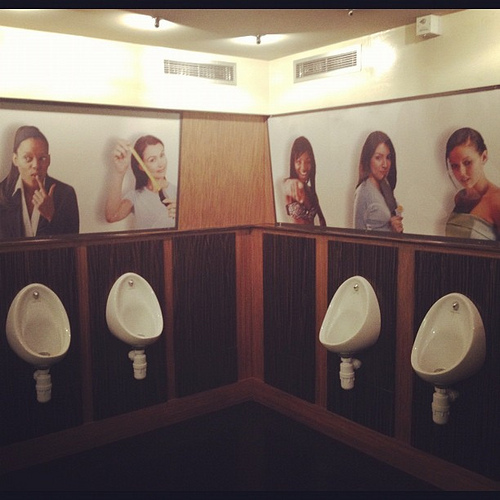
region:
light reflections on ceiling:
[113, 9, 305, 65]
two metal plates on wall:
[159, 45, 365, 109]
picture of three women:
[271, 95, 498, 230]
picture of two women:
[2, 104, 183, 244]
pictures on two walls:
[2, 86, 498, 465]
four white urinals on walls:
[5, 268, 483, 381]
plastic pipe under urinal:
[412, 346, 478, 425]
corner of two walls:
[203, 55, 312, 417]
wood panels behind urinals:
[4, 228, 498, 470]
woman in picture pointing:
[268, 129, 335, 229]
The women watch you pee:
[22, 103, 483, 273]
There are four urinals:
[7, 252, 487, 425]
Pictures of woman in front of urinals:
[26, 109, 494, 413]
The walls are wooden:
[75, 225, 390, 460]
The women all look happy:
[10, 109, 488, 286]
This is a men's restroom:
[14, 80, 494, 448]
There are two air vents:
[100, 33, 377, 125]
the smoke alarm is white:
[412, 10, 443, 50]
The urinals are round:
[417, 287, 477, 433]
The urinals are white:
[294, 279, 387, 378]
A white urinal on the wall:
[317, 273, 379, 394]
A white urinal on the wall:
[404, 291, 482, 428]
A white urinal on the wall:
[106, 271, 165, 381]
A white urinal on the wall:
[6, 282, 73, 404]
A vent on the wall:
[290, 48, 359, 84]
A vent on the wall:
[158, 55, 238, 85]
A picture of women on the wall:
[266, 90, 498, 250]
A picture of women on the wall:
[0, 104, 182, 230]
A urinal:
[408, 290, 486, 425]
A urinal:
[317, 273, 383, 389]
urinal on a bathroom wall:
[321, 252, 386, 416]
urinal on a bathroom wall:
[400, 268, 492, 445]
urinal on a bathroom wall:
[92, 246, 167, 406]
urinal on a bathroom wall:
[3, 267, 87, 427]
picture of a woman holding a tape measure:
[97, 127, 179, 238]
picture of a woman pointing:
[275, 134, 335, 234]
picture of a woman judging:
[432, 121, 499, 243]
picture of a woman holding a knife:
[348, 124, 410, 238]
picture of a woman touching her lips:
[0, 118, 80, 245]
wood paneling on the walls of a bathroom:
[180, 231, 310, 403]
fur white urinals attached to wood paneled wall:
[8, 266, 488, 425]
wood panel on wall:
[252, 228, 321, 407]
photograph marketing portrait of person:
[1, 104, 82, 244]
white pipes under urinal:
[121, 350, 157, 381]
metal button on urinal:
[30, 288, 46, 302]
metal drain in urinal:
[432, 359, 447, 376]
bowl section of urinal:
[313, 302, 384, 350]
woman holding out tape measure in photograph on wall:
[100, 123, 182, 233]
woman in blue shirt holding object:
[343, 125, 413, 237]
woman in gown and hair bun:
[433, 123, 499, 245]